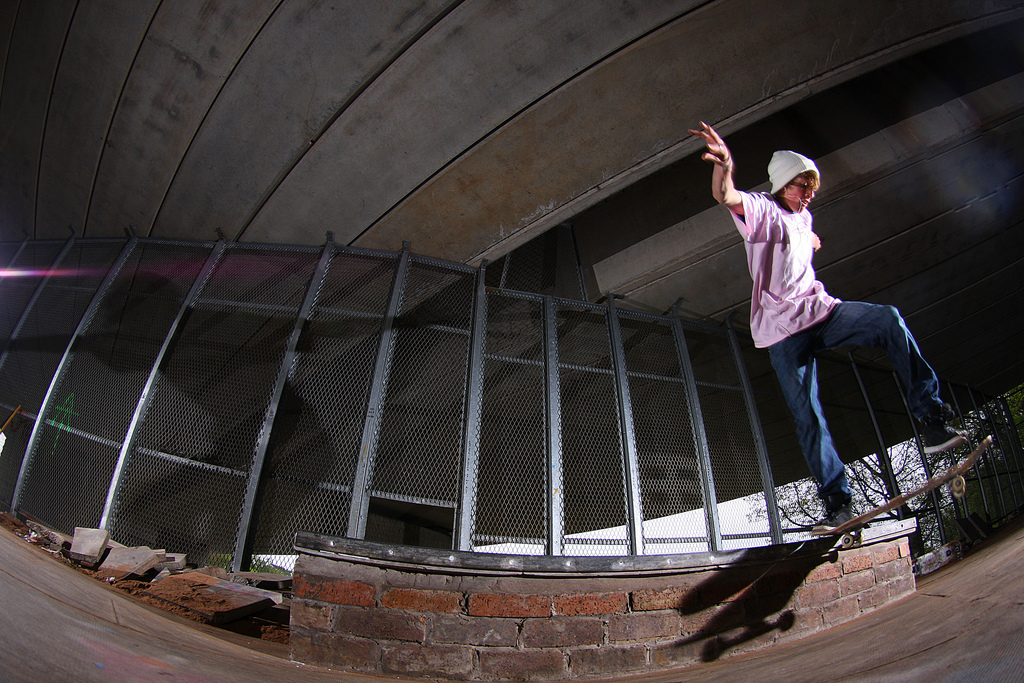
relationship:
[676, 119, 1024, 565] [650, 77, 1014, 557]
kid perform trick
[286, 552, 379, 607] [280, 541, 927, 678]
brick in wall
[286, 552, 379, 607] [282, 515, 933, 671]
brick in wall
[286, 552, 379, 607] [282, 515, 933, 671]
brick on wall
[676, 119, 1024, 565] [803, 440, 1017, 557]
kid riding skateboard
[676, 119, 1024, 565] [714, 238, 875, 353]
kid wearing shirt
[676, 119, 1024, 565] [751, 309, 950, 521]
kid wearing jeans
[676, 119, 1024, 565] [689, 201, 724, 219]
kid has arm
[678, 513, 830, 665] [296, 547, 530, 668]
shadow on bricks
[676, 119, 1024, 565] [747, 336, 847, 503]
kid has leg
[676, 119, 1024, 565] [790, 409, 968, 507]
kid wearing shoes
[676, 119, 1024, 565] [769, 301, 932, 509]
kid wearing pants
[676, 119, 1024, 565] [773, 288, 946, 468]
kid wearing pants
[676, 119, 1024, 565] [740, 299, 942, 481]
kid wearing pants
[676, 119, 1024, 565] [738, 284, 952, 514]
kid wearing jeans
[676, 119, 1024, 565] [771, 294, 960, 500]
kid wearing jeans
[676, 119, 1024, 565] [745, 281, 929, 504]
kid wearing jeans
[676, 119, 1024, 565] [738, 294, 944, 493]
kid wearing jeans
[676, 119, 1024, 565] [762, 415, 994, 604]
kid on skateboard